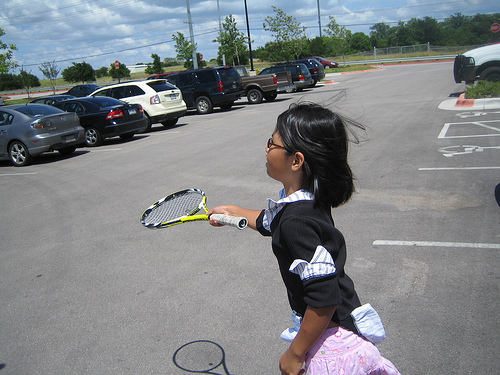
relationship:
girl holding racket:
[208, 104, 399, 374] [140, 186, 249, 231]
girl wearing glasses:
[208, 104, 399, 374] [267, 137, 288, 153]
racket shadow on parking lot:
[172, 338, 231, 375] [0, 63, 499, 373]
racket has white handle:
[140, 186, 249, 231] [211, 214, 250, 231]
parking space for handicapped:
[417, 135, 500, 171] [437, 143, 499, 161]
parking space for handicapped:
[443, 106, 500, 124] [454, 109, 499, 120]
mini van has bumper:
[256, 63, 315, 92] [293, 79, 313, 87]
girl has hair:
[208, 104, 399, 374] [276, 104, 358, 211]